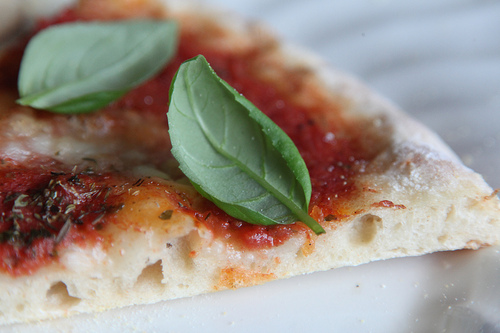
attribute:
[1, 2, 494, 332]
plate — silver, white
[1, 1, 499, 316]
crust — white, thin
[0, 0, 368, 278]
sauce — red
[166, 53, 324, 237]
leaf — curled, small, basil, green, fresh, upside down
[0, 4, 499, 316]
pizza — sliced, appetizing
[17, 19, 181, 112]
leaf — basil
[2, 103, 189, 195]
cheese — melted